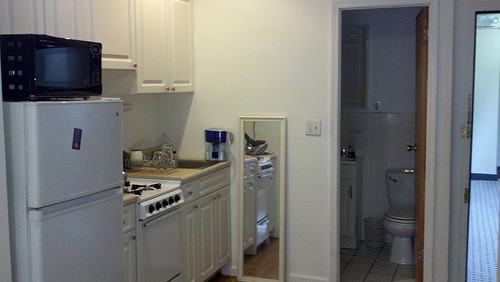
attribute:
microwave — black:
[1, 31, 106, 100]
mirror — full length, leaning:
[461, 6, 499, 282]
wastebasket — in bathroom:
[361, 217, 385, 250]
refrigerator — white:
[1, 96, 128, 282]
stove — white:
[126, 172, 192, 281]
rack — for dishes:
[122, 147, 177, 176]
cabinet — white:
[341, 162, 365, 252]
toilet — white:
[379, 166, 420, 268]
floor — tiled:
[340, 241, 419, 281]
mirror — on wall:
[340, 24, 374, 112]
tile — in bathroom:
[345, 253, 380, 265]